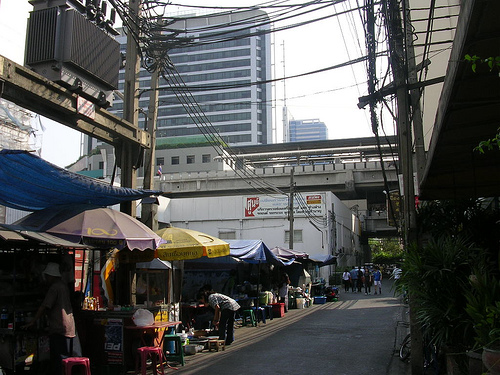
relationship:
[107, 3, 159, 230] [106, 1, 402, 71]
pole with lines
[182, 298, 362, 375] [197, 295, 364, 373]
shadow of lines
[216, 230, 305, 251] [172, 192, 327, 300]
windows on side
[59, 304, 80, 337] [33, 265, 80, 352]
sun on man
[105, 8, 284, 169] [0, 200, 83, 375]
building behind restaurants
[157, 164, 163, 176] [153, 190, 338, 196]
flag on top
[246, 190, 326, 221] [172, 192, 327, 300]
sign on side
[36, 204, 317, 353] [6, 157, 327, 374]
restaurants and market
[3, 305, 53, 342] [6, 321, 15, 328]
part of pepsi sign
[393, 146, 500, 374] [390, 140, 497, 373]
bunch of bush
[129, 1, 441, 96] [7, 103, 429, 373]
wires above street